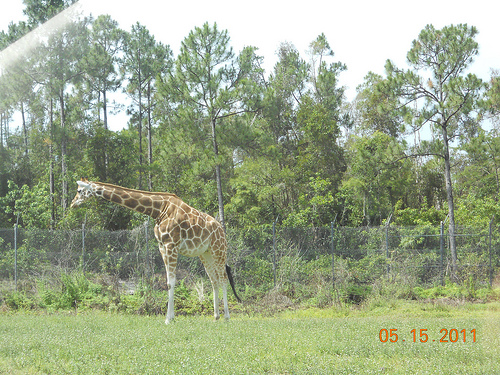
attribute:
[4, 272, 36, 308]
bush — low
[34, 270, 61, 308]
bush — low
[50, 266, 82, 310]
bush — low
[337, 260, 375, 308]
bush — low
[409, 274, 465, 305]
bush — low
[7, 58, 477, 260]
area — large, wooded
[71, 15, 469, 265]
area — large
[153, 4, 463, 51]
sky — white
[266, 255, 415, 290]
shrubs — green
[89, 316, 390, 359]
grass — green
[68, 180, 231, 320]
giraffe — standing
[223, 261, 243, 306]
tail — long, black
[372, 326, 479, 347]
watermark — orange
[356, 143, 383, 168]
leaves — green 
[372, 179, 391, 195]
leaves — green 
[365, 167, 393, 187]
leaves — green 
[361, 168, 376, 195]
leaves — green 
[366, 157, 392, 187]
leaves — green 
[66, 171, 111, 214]
head — giraffes 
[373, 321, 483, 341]
photo — date 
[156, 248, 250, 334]
legs — giraffes 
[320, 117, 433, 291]
tree —  far right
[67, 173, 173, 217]
giraffe — long neck 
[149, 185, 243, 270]
giraffe — body 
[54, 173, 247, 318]
giraffe — feet 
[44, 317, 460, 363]
grass — green 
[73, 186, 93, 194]
eyeball — giraffes 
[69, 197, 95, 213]
nose — giraffes 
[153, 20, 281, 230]
tree — large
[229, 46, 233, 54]
needle — green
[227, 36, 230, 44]
needle — green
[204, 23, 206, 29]
needle — green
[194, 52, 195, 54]
needle — green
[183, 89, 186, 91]
needle — green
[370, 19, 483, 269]
tree — large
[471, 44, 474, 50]
needle — green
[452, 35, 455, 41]
needle — green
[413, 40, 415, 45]
needle — green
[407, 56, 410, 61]
needle — green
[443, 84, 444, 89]
needle — green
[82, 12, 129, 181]
tree — large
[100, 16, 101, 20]
needle — green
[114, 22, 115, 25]
needle — green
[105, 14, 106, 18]
needle — green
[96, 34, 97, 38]
needle — green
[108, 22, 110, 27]
needle — green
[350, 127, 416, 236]
tree — large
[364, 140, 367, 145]
leaf — green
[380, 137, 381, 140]
leaf — green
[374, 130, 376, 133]
leaf — green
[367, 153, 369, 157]
leaf — green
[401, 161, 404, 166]
leaf — green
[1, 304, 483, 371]
area — grassy, open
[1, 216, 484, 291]
fence — mesh, gray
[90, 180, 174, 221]
neck — long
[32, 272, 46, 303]
weed — growing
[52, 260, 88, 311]
shrub — growing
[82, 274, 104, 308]
shrub — growing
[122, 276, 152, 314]
shrub — growing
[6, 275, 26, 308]
shrub — growing